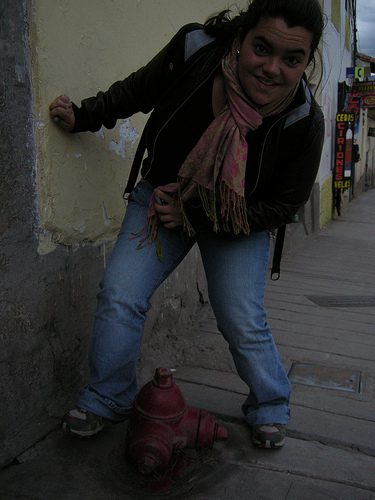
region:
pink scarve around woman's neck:
[177, 55, 253, 244]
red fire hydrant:
[123, 364, 232, 487]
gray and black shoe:
[236, 405, 294, 462]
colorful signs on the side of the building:
[325, 62, 373, 220]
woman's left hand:
[45, 90, 78, 138]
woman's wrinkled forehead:
[251, 15, 316, 52]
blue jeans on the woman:
[56, 190, 299, 383]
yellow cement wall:
[24, 149, 116, 262]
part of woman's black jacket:
[262, 130, 301, 228]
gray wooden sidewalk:
[311, 255, 357, 330]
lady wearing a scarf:
[40, 7, 342, 476]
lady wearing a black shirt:
[57, 2, 370, 447]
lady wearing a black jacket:
[76, 1, 349, 475]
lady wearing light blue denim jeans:
[67, 3, 372, 468]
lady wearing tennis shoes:
[66, 1, 320, 467]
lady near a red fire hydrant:
[58, 3, 370, 498]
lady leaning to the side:
[37, 1, 372, 483]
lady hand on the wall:
[27, 0, 373, 253]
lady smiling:
[183, 1, 342, 145]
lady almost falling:
[49, 2, 317, 497]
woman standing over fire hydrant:
[49, 0, 326, 453]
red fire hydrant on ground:
[115, 361, 230, 494]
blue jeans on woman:
[80, 178, 294, 422]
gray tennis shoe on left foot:
[251, 420, 281, 450]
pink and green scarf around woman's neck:
[174, 40, 295, 240]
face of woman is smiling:
[238, 10, 310, 108]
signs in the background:
[332, 65, 372, 221]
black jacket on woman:
[74, 21, 323, 241]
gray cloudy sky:
[351, 0, 371, 57]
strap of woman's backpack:
[268, 213, 287, 282]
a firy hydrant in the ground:
[57, 335, 289, 496]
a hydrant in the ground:
[67, 342, 273, 484]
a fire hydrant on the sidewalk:
[84, 356, 283, 497]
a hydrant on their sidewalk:
[65, 336, 268, 498]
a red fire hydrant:
[106, 336, 279, 472]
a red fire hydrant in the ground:
[110, 343, 241, 483]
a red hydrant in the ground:
[79, 324, 290, 483]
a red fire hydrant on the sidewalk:
[102, 337, 268, 490]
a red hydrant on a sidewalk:
[89, 336, 291, 490]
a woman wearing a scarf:
[134, 12, 347, 255]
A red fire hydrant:
[105, 360, 235, 496]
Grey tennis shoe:
[241, 418, 292, 450]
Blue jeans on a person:
[76, 180, 302, 450]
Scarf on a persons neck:
[135, 75, 277, 250]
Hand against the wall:
[40, 83, 111, 148]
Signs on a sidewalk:
[330, 70, 368, 217]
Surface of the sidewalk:
[278, 301, 331, 336]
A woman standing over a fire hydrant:
[39, 2, 355, 473]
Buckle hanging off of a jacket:
[264, 225, 291, 285]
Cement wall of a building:
[13, 290, 66, 365]